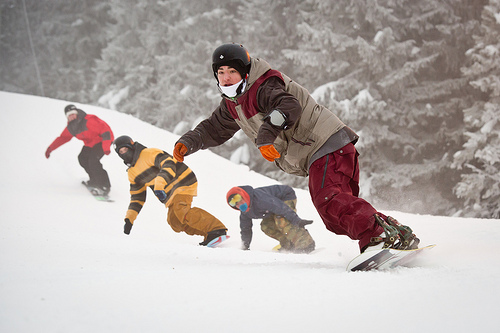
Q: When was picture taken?
A: Daytime.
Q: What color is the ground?
A: White.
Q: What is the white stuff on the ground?
A: Snow.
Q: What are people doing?
A: Snowboarding.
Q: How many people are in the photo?
A: Four.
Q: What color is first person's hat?
A: Black.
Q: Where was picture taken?
A: Ski slope.